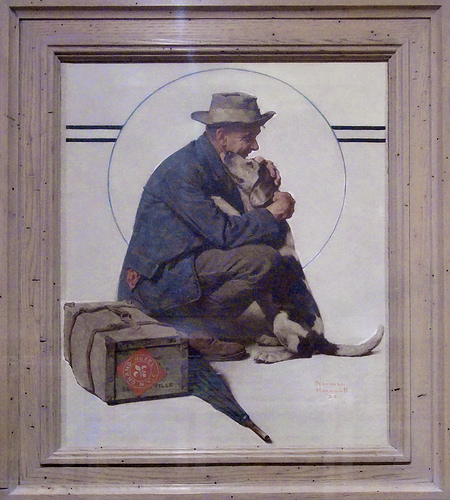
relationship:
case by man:
[59, 298, 192, 407] [114, 91, 291, 358]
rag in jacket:
[123, 267, 143, 294] [108, 133, 280, 318]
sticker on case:
[117, 346, 167, 401] [59, 298, 192, 407]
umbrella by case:
[187, 338, 271, 447] [59, 298, 192, 407]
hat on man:
[186, 92, 276, 131] [114, 91, 291, 358]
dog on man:
[207, 148, 384, 370] [114, 91, 291, 358]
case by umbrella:
[59, 298, 192, 407] [187, 338, 271, 447]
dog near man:
[207, 148, 384, 370] [114, 91, 291, 358]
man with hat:
[114, 91, 291, 358] [186, 92, 276, 131]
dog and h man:
[207, 148, 384, 370] [114, 91, 291, 358]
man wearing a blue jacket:
[114, 91, 291, 358] [108, 133, 280, 318]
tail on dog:
[320, 329, 385, 357] [207, 148, 384, 370]